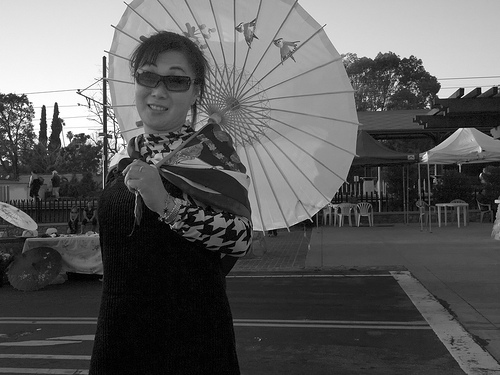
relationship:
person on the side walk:
[65, 206, 84, 234] [318, 236, 470, 371]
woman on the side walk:
[89, 29, 256, 374] [308, 218, 472, 373]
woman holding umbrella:
[89, 122, 252, 371] [106, 2, 361, 237]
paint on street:
[341, 260, 485, 357] [1, 267, 499, 372]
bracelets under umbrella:
[160, 196, 185, 225] [342, 129, 417, 169]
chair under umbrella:
[353, 200, 376, 228] [342, 129, 417, 169]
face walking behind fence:
[26, 167, 63, 181] [5, 189, 395, 226]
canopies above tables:
[360, 130, 499, 168] [434, 200, 476, 228]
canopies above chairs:
[360, 130, 499, 168] [332, 205, 376, 227]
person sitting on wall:
[82, 201, 98, 234] [0, 220, 102, 240]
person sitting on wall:
[65, 206, 84, 234] [0, 220, 102, 240]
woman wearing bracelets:
[89, 29, 256, 374] [158, 195, 185, 227]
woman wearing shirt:
[89, 29, 256, 374] [132, 136, 242, 251]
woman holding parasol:
[89, 29, 256, 374] [94, 1, 363, 236]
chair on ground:
[353, 199, 377, 229] [1, 229, 498, 370]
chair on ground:
[416, 199, 436, 226] [1, 229, 498, 370]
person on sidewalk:
[65, 206, 82, 234] [250, 226, 498, 370]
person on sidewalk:
[22, 172, 44, 198] [2, 219, 499, 269]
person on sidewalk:
[46, 166, 61, 197] [2, 219, 499, 269]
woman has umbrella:
[89, 29, 256, 374] [106, 2, 361, 237]